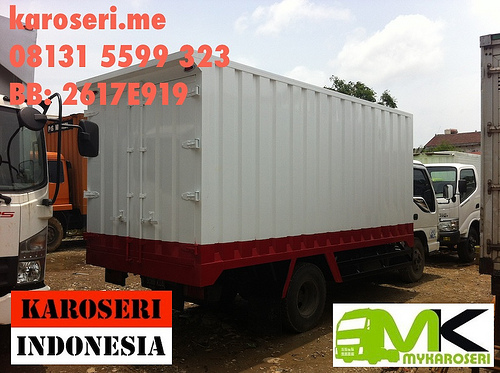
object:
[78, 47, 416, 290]
storage box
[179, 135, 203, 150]
latches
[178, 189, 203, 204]
hinges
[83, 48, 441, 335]
truck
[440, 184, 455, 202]
mirror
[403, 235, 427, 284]
wheels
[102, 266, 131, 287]
mud flaps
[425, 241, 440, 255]
bumper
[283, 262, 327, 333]
tire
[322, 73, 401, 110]
tree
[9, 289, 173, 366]
logo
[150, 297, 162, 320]
letters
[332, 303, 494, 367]
logo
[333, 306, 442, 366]
design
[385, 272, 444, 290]
shadow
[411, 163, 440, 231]
door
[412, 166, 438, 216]
window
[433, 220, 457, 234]
light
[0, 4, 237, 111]
ad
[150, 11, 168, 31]
letters